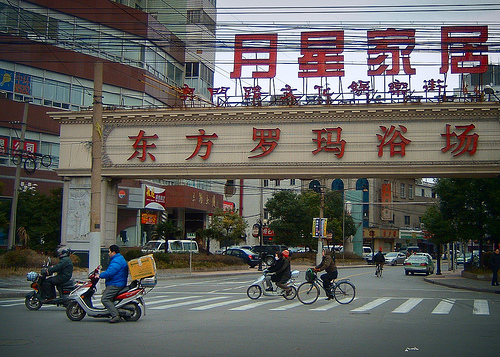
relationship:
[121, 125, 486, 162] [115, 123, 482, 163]
writing on arch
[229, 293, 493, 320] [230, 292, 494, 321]
road white stripes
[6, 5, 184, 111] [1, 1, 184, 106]
building with windows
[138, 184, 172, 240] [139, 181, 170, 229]
signs in store front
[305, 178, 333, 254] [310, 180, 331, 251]
lights next to road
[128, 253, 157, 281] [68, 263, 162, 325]
cardboard on motorcycle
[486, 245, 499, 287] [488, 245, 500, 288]
person on sidewalk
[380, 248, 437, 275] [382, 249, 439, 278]
vehicles on road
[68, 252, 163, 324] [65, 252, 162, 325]
motorcycle with package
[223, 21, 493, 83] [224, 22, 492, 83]
oriental writing over structure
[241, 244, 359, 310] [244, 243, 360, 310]
people on bicycles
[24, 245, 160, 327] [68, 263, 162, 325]
people on motorcycle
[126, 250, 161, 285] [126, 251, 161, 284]
cardboard carrying items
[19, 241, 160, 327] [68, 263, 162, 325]
silver and red motorcycle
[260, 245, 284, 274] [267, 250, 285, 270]
person with mask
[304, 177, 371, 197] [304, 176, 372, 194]
arches on building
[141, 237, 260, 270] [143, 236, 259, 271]
vehicles in background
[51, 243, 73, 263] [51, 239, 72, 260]
cap on person head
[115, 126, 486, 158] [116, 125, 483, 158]
writing on structure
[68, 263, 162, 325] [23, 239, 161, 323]
motorcycle crossing street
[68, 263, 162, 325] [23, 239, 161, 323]
motorcycle in street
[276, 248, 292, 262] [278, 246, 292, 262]
person wearing orange cap